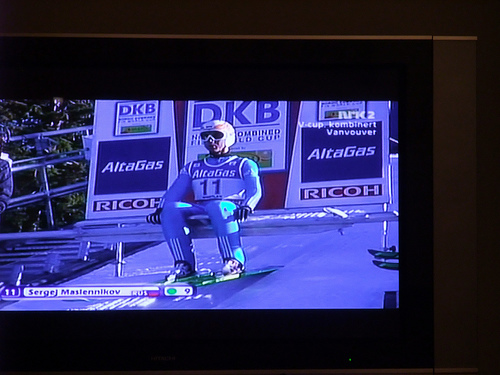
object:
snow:
[84, 252, 368, 306]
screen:
[46, 97, 409, 317]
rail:
[3, 118, 93, 231]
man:
[146, 118, 263, 280]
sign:
[298, 182, 384, 200]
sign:
[91, 195, 161, 211]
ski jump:
[0, 263, 288, 301]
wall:
[4, 223, 399, 312]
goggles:
[199, 130, 224, 140]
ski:
[153, 265, 277, 288]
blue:
[146, 151, 265, 273]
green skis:
[165, 256, 281, 285]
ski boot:
[164, 261, 194, 281]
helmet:
[196, 118, 237, 148]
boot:
[150, 225, 200, 287]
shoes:
[220, 254, 246, 276]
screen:
[0, 99, 400, 311]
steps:
[1, 220, 116, 283]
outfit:
[156, 153, 264, 265]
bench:
[73, 118, 398, 277]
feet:
[166, 261, 192, 275]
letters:
[90, 183, 386, 215]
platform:
[49, 141, 398, 263]